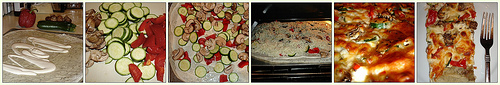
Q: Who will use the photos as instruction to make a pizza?
A: An amateur chef.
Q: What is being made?
A: Pizza.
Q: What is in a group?
A: Photos.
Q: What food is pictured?
A: Pizza.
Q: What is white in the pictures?
A: Cheese.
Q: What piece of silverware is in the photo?
A: Fork.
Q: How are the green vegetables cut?
A: Slices.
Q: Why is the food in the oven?
A: Getting cooked.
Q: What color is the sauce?
A: White.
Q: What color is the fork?
A: Silver.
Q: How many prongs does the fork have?
A: Four.